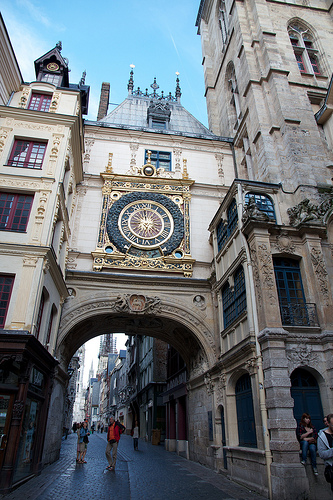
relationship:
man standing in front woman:
[102, 413, 132, 476] [72, 419, 104, 469]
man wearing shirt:
[102, 413, 132, 476] [107, 424, 124, 443]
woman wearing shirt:
[72, 419, 104, 469] [77, 426, 94, 442]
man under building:
[102, 413, 132, 476] [1, 36, 325, 431]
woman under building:
[72, 419, 104, 469] [1, 36, 325, 431]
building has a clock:
[1, 36, 325, 431] [98, 184, 195, 260]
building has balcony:
[1, 36, 325, 431] [195, 177, 285, 247]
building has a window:
[1, 36, 325, 431] [284, 17, 329, 82]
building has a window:
[1, 36, 325, 431] [217, 79, 250, 130]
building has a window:
[1, 36, 325, 431] [8, 132, 52, 168]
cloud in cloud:
[14, 8, 63, 56] [0, 0, 208, 130]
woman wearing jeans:
[298, 419, 325, 471] [300, 437, 319, 465]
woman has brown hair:
[298, 419, 325, 471] [298, 415, 312, 422]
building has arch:
[1, 36, 325, 431] [60, 296, 217, 358]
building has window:
[1, 36, 325, 431] [0, 182, 34, 235]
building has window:
[1, 36, 325, 431] [230, 371, 266, 449]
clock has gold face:
[98, 184, 195, 260] [118, 200, 175, 247]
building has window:
[1, 36, 325, 431] [284, 371, 329, 434]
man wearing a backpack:
[102, 413, 132, 476] [118, 423, 132, 434]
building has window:
[1, 36, 325, 431] [28, 86, 66, 114]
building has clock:
[1, 36, 325, 431] [47, 61, 61, 69]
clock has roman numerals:
[98, 184, 195, 260] [127, 202, 157, 214]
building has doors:
[1, 36, 325, 431] [156, 393, 199, 460]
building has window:
[1, 36, 325, 431] [219, 272, 253, 327]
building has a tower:
[1, 36, 325, 431] [27, 42, 72, 91]